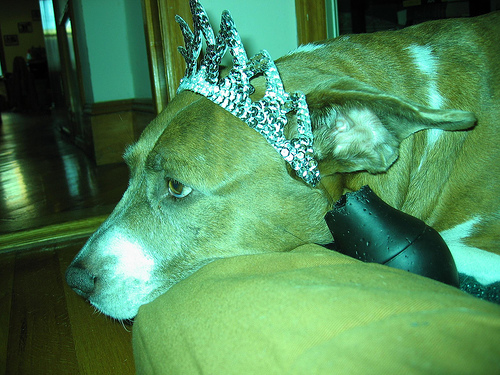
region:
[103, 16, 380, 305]
the dog is wearing a tiara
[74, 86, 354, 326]
the dog is brown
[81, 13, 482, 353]
the dog is brown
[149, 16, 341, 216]
silver head band on dog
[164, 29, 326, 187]
dog wearing silver head band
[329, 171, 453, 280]
black toy beside dog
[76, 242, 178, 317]
white fur on dog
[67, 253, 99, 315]
black nose on dog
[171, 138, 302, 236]
brown fur on dog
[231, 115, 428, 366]
dog on tan couch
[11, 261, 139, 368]
dark wood on floor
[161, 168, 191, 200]
brown eye on dog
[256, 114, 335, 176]
diamonds on head band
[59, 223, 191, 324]
white black and brown muzzle of a dog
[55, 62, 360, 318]
dogs head laying on the arm of a sofa or chair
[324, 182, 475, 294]
black toy of a dog with chewed up end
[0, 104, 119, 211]
dark wood flooring with reflected light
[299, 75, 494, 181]
left ear of a brown and white dog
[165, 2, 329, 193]
silver crown on the head of a brown and white dog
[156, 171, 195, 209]
left eye of a brown and white dog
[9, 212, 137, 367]
brown wood flooring in room with a dog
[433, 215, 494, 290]
white patch of fur on a brown dog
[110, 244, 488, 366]
ten arm of couch or chair with dog's head on it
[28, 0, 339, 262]
dog is wearing a crown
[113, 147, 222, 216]
the eye is open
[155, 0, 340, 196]
the crown is silver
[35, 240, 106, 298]
the nose is black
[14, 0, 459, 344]
the dog is resting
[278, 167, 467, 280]
a black object by the dog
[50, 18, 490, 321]
the dog is brown and white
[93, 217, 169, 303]
white patch by the nose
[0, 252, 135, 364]
the floor is brown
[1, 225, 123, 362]
the floor is made of wood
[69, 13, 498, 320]
Sad looking large dog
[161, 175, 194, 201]
Brown eye of a dog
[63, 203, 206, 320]
Dog's brown and white muzzle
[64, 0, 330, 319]
Sequined crown on a dog's head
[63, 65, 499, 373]
Dog's head lying on the back of a couch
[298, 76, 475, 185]
Large, floppy, brown dog's ear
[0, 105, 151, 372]
Hardwood floors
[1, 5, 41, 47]
Three pictures on a wall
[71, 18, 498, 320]
Dog with short brown fur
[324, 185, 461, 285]
Chewed-up, black dog toy